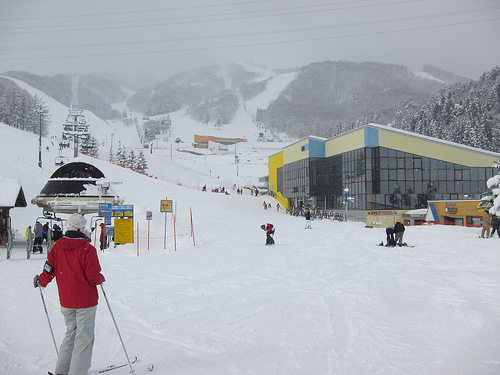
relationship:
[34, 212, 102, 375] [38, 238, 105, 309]
person wearing jacket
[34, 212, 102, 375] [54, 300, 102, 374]
person wearing pants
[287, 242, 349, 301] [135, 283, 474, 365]
snow covering ground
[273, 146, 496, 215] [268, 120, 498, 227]
window on building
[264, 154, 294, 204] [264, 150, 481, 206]
yellow portion with many windows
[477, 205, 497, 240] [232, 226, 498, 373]
person standing in snow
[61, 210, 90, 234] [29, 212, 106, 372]
head of person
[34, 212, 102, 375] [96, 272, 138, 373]
person holding ski pole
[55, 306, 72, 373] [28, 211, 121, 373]
leg of person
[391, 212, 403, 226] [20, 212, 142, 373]
head of person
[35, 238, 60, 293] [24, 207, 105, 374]
arm of person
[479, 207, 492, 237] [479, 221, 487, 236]
person has leg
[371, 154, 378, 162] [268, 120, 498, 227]
window on building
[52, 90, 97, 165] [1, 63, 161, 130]
ski chair up mountain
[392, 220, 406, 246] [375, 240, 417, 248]
person putting on equipment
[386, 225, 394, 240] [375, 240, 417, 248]
skier putting on equipment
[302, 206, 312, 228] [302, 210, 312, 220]
skier wearing jacket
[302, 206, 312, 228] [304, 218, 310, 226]
skier wearing pants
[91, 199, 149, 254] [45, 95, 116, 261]
signs near start of lift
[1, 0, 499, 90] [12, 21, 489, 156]
sky over mountains